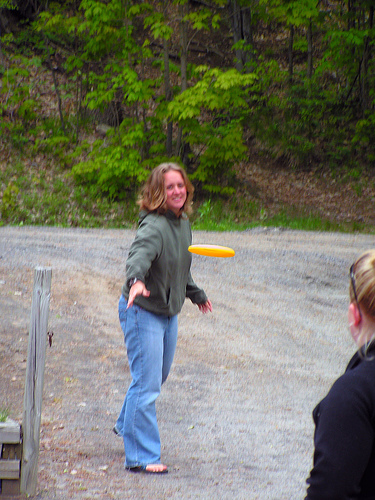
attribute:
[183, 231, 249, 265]
frisbee — yellow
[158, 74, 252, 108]
leaves — green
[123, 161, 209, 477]
girl — barefoot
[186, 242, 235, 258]
frisbee — yellow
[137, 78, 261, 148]
leaves — green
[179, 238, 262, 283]
frisbee — yellow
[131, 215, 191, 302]
hoodie — green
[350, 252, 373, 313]
hair — blonde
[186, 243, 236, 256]
flying disc — yellow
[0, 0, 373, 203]
bushes — green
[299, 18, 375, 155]
leaves — green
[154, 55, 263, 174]
leaves — green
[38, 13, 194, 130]
leaves — green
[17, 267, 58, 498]
fence post — beige colored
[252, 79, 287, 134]
leaves —  green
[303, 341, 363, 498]
top — dark colored